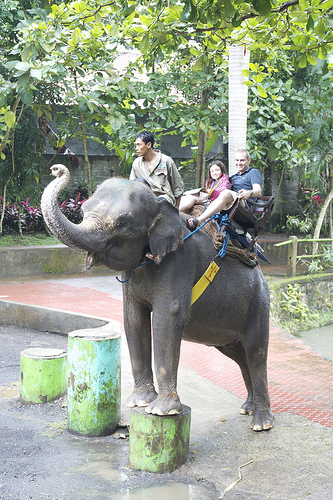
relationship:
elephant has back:
[53, 178, 283, 426] [169, 206, 275, 294]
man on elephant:
[129, 126, 183, 211] [53, 178, 283, 426]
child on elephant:
[205, 159, 231, 204] [53, 178, 283, 426]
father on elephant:
[174, 147, 264, 230] [53, 178, 283, 426]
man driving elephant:
[135, 119, 187, 218] [53, 178, 283, 426]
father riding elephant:
[224, 141, 266, 213] [53, 178, 283, 426]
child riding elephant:
[205, 159, 231, 204] [53, 178, 283, 426]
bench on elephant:
[225, 199, 275, 244] [53, 178, 283, 426]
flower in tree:
[303, 185, 323, 209] [161, 12, 329, 176]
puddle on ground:
[128, 484, 214, 500] [25, 407, 333, 499]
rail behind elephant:
[278, 232, 332, 254] [53, 178, 283, 426]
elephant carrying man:
[53, 178, 283, 426] [129, 126, 183, 211]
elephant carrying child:
[53, 178, 283, 426] [205, 159, 231, 204]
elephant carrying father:
[53, 178, 283, 426] [174, 147, 264, 230]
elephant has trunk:
[53, 178, 283, 426] [45, 160, 87, 240]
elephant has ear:
[53, 178, 283, 426] [148, 190, 186, 259]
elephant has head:
[53, 178, 283, 426] [76, 182, 163, 269]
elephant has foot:
[53, 178, 283, 426] [156, 377, 185, 422]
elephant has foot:
[53, 178, 283, 426] [251, 410, 280, 437]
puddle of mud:
[128, 484, 214, 500] [150, 485, 180, 499]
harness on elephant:
[187, 224, 236, 292] [53, 178, 283, 426]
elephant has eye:
[53, 178, 283, 426] [104, 213, 133, 230]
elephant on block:
[53, 178, 283, 426] [128, 403, 188, 472]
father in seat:
[174, 147, 264, 230] [225, 199, 275, 244]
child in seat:
[211, 151, 234, 222] [225, 199, 275, 244]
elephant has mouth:
[53, 178, 283, 426] [75, 240, 103, 273]